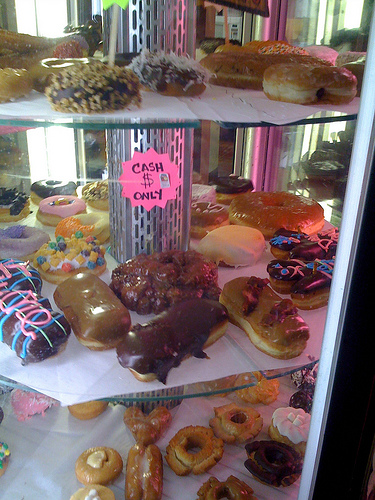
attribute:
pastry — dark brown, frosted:
[1, 254, 46, 295]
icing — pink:
[55, 205, 76, 214]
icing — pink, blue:
[269, 231, 300, 243]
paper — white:
[1, 391, 284, 497]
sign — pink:
[117, 146, 184, 212]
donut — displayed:
[213, 405, 262, 436]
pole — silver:
[313, 99, 360, 294]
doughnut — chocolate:
[44, 61, 143, 114]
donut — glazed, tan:
[36, 238, 96, 269]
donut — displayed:
[260, 402, 317, 450]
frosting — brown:
[266, 266, 281, 280]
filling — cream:
[84, 448, 107, 468]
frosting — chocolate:
[112, 296, 226, 386]